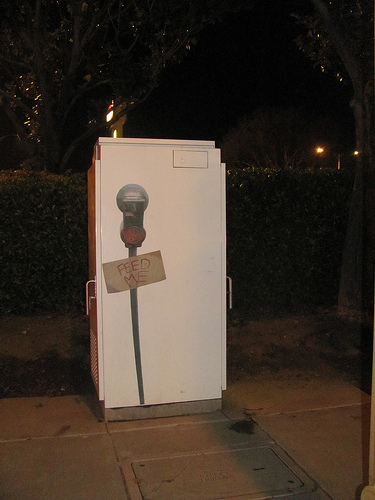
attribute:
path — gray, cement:
[7, 377, 375, 499]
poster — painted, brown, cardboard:
[98, 249, 179, 293]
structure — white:
[77, 127, 239, 424]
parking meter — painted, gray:
[116, 182, 156, 410]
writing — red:
[118, 258, 155, 287]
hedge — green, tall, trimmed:
[1, 172, 346, 317]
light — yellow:
[316, 140, 328, 156]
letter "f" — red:
[116, 262, 128, 277]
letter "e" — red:
[129, 261, 140, 270]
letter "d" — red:
[140, 258, 153, 270]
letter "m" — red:
[120, 272, 139, 291]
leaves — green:
[289, 192, 301, 231]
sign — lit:
[107, 95, 127, 127]